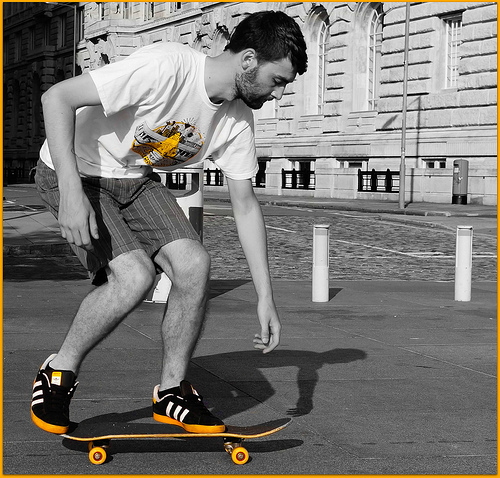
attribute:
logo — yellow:
[126, 117, 197, 179]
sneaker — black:
[150, 381, 225, 435]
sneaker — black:
[30, 349, 80, 434]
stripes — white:
[165, 401, 189, 423]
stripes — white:
[29, 378, 42, 406]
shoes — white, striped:
[152, 386, 232, 442]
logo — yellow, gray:
[127, 116, 208, 177]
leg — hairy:
[152, 235, 209, 382]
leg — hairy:
[78, 258, 137, 336]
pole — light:
[397, 1, 412, 214]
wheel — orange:
[231, 445, 251, 468]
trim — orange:
[152, 413, 224, 430]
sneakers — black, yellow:
[31, 388, 224, 428]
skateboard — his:
[46, 403, 316, 475]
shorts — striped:
[36, 159, 205, 269]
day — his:
[14, 7, 480, 460]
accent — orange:
[28, 366, 293, 466]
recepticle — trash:
[132, 167, 206, 299]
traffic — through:
[302, 200, 312, 207]